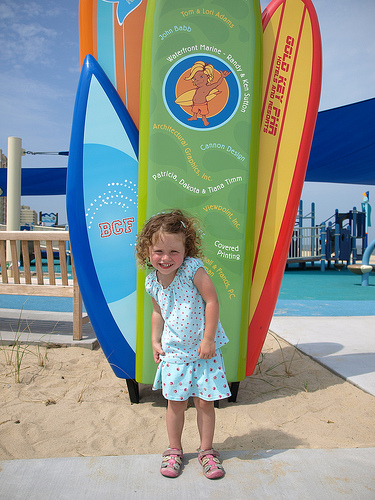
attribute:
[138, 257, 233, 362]
shirt — poka dot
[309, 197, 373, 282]
playground — metal, blue, grey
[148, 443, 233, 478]
croc sandals — pink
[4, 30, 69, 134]
skies — blue, partly cloudy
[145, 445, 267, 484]
sandal — pink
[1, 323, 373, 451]
sand — brown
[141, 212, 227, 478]
child — smiling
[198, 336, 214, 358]
hand — female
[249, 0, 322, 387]
sign — yellow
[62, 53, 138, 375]
surfboard — blue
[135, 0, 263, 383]
sign — green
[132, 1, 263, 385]
surfboard — green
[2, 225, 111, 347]
bench — tan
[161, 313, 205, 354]
outfit — blue, pink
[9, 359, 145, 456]
sand — tan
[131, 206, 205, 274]
hair — brown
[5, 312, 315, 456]
area — sandy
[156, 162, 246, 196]
lettering — white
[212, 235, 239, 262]
lettering — white